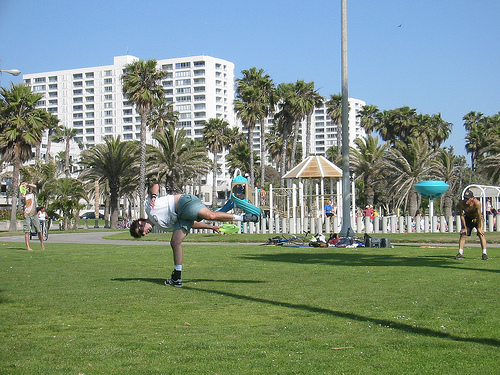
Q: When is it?
A: Day time.